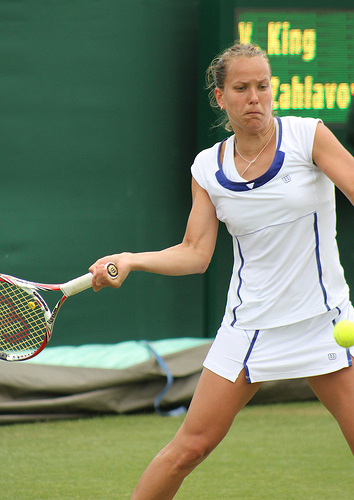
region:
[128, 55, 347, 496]
Female tennis player.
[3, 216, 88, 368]
Red and white tennis racket.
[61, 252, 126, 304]
Right hand, gripping white racket handle.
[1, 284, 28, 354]
Red W detail on racket face.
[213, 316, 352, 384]
Blue and white tennis skirt.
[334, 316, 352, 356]
Yellow tennis ball near player.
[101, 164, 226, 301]
Right arm outflung to hit ball.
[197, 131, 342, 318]
Blue and white tennis top with white tank under it.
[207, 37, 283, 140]
Agitated face with pulled-back blonde hair.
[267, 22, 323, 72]
Yellow word, "king" on green sign.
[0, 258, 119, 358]
White and red tennis racket.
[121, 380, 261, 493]
A human knee and leg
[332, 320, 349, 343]
A yellow tennis ball.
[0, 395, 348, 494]
Field of Green grass.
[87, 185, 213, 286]
A human arm and hand.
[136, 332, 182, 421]
A blue strap.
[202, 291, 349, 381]
A blue and white skirt with a W on the front.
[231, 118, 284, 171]
A silver necklace around her neck.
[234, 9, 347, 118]
Green and yellow sign.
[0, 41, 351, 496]
A lady playing tennis.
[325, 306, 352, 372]
green tennis ball in the air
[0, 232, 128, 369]
tennis racket being swung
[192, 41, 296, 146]
tennis player's face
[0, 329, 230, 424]
rolled up tarp on the ground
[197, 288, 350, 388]
white and blue tennis skirt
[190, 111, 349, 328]
white and blue shirt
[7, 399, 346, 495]
grassy tennis court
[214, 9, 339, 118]
green scoreboard with yellow letters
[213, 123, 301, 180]
white necklace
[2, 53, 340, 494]
caucasian woman playing tennis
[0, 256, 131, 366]
Tennis racquet ready to swing at tennis ball.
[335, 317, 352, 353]
A yellow tennis ball.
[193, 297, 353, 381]
A tennis skirt.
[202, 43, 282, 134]
A woman's face concentrating on hitting the tennis ball.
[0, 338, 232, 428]
A tarp with a blue strap is in the background.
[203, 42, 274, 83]
A woman's hair is pulled back away from her face.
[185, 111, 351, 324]
A white tennis shirt with blue edgings.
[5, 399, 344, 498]
Green turf covering tennis court.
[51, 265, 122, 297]
The handle of a tennis racquet.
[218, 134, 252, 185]
A small inner shirt shown underneath the tennis shirt.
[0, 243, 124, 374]
A tennis racket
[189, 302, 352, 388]
A white and blue skirt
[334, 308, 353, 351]
tennis ball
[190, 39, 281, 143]
A woman's face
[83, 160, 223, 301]
A woman's arm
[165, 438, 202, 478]
knee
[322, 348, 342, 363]
"W" on skirt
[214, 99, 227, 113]
small earring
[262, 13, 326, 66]
King written in yellow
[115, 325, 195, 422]
A blue strap in background